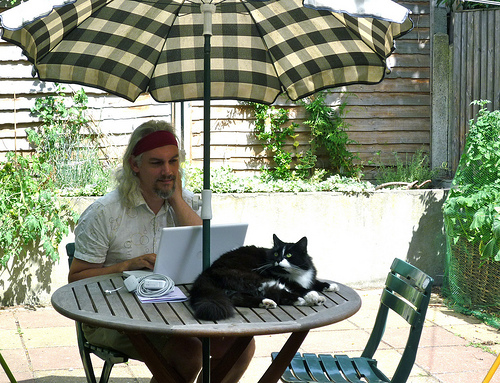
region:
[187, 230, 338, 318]
a cat laying on a table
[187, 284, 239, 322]
the tail of a cat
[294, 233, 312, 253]
the ear of a cat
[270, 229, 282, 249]
the ear of a cat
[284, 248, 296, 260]
the eye of a cat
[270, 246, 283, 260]
the eye of a cat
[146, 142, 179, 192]
the face of a man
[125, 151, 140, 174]
the ear of a man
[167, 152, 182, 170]
the eye of a man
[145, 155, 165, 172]
the eye of a man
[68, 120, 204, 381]
Man sitting at an outdoor table.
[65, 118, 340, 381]
Man sitting at an outdoor table with a cat.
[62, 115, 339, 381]
Man using computer outdoors.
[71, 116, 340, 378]
Man and cat sharing outdoor table.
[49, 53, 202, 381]
Man sitting outdoors under umbrella.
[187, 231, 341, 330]
Cat sitting on outdoor table.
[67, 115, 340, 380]
Man sitting near cat.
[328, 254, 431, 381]
Vacant outdoor chair.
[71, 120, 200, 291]
Man working on computer outside.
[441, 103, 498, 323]
Plants growing in outdoor living space.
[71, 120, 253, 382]
a man sitting at a patio table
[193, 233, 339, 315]
a cat laying on a patio table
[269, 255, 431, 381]
a green patio chair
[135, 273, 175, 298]
rolled white wires on a table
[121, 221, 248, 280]
a white laptop on a table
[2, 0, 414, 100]
a yellow and black umbrella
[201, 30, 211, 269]
green pole of an umbrella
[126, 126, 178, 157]
man wearing a red headband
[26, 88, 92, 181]
ivy on a wooden wall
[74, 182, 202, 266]
man wearing a white button-down shirt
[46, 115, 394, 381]
Man sitting at patio table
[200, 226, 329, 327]
cat sitting on patio table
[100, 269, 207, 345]
A charger laying next to laptop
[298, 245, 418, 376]
green plastic patio chair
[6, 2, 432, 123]
a green and white plaid umbrella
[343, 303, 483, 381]
red brick pavers for patio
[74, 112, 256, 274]
man using a laptop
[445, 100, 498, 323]
green plant with netting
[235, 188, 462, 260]
brick retaining wall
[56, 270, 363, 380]
brown plastic patio table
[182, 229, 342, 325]
The cat is black and white.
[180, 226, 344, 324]
The cat has green eyes.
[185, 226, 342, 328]
The cat is furry.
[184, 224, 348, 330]
The cat is long haired.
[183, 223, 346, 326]
The cat is lying down.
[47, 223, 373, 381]
The cat is on the table.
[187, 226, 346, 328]
The cat is alert.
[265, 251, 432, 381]
The chair is green.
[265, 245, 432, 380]
The chair is vacant.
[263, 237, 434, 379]
The chair is empty.